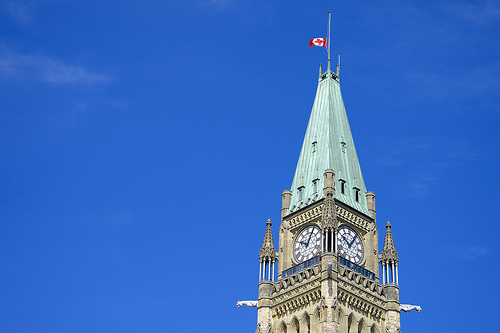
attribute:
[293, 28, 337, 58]
flag — red, whit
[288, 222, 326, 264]
clock — saying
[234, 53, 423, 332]
tower — building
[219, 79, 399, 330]
structure — pointed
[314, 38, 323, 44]
cross — red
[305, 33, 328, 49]
flag — Canadian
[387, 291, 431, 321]
gargoyle — grey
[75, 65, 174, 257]
sky — bright, blue, sunny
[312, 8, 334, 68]
pole — metal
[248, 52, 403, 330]
building — tall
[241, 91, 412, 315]
tower — clock, building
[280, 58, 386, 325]
tower — blue, pointed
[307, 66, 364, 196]
roof — light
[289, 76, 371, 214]
cap — green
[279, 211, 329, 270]
clock — round , white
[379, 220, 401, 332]
column — thin, grey, concrete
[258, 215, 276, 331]
column — thin, grey, concrete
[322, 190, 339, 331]
column — thin, grey, concrete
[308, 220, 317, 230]
numeral — black, Roman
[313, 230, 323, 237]
numeral — black, Roman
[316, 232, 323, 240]
numeral — black, Roman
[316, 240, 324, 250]
numeral — black, Roman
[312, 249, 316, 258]
numeral — black, Roman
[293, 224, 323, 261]
face — clock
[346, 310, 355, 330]
window — small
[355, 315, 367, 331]
window — small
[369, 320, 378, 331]
window — small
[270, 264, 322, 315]
trim — decorative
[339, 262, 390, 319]
trim — decorative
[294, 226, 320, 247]
10:05 — time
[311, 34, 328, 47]
cross — red